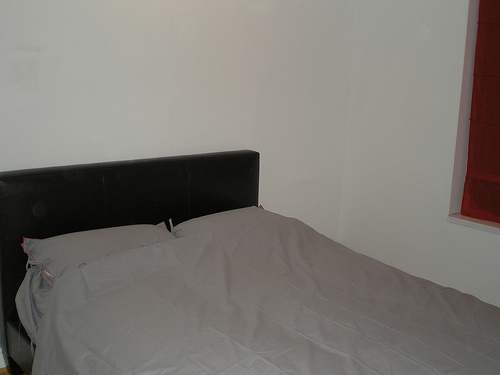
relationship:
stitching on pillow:
[15, 236, 51, 288] [17, 221, 177, 303]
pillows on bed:
[23, 220, 209, 295] [0, 145, 499, 373]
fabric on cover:
[29, 240, 494, 373] [30, 213, 499, 373]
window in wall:
[445, 2, 498, 235] [4, 5, 497, 300]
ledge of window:
[431, 198, 491, 235] [416, 3, 498, 155]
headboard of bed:
[2, 150, 263, 294] [121, 202, 275, 337]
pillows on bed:
[7, 220, 211, 282] [0, 145, 499, 373]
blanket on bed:
[0, 203, 499, 373] [79, 252, 210, 371]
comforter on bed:
[5, 197, 499, 372] [0, 145, 499, 373]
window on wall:
[445, 2, 499, 223] [337, 1, 499, 308]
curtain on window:
[462, 31, 499, 223] [455, 3, 498, 221]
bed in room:
[0, 145, 499, 373] [1, 0, 498, 365]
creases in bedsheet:
[191, 287, 269, 329] [53, 254, 498, 374]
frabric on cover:
[127, 251, 285, 323] [30, 213, 499, 373]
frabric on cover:
[271, 287, 409, 372] [30, 213, 499, 373]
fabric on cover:
[29, 240, 494, 373] [168, 292, 279, 356]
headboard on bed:
[49, 141, 258, 229] [46, 170, 498, 372]